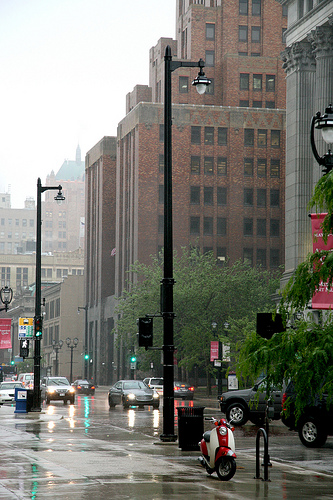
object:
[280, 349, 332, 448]
vehicles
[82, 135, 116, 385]
buildings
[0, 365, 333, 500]
street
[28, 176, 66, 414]
lamp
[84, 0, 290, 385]
building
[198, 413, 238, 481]
motorbike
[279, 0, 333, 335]
building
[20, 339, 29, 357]
crossing signal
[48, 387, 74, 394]
headlights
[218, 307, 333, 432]
branches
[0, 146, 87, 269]
mist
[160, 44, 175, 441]
posts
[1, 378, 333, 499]
ground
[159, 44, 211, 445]
street light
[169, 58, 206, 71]
pole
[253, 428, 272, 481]
barrier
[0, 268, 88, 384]
buildings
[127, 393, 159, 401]
headlights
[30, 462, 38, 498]
reflection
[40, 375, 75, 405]
cars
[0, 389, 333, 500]
road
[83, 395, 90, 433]
light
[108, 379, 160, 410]
car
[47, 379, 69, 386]
windshield wipers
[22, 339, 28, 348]
pedstrian signal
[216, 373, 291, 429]
suv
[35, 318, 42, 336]
light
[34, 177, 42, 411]
pole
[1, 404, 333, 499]
sidewalk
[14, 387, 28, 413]
newspaper box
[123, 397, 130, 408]
tire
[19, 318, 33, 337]
banner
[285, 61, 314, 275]
column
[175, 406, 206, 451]
garbage can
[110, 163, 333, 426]
trees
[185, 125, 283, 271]
windows